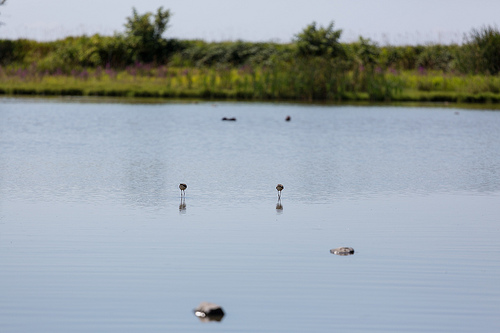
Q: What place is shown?
A: It is a lake.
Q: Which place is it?
A: It is a lake.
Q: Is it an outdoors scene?
A: Yes, it is outdoors.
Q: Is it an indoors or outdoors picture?
A: It is outdoors.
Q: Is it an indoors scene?
A: No, it is outdoors.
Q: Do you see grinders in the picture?
A: No, there are no grinders.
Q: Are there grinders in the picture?
A: No, there are no grinders.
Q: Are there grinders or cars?
A: No, there are no grinders or cars.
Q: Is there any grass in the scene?
A: Yes, there is grass.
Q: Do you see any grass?
A: Yes, there is grass.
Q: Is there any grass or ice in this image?
A: Yes, there is grass.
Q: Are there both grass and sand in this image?
A: No, there is grass but no sand.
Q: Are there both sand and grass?
A: No, there is grass but no sand.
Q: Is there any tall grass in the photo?
A: Yes, there is tall grass.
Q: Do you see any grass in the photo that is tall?
A: Yes, there is grass that is tall.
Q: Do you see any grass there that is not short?
A: Yes, there is tall grass.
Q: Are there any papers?
A: No, there are no papers.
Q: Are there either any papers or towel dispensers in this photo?
A: No, there are no papers or towel dispensers.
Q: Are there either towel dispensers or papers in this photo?
A: No, there are no papers or towel dispensers.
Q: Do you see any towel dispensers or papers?
A: No, there are no papers or towel dispensers.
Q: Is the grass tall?
A: Yes, the grass is tall.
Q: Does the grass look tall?
A: Yes, the grass is tall.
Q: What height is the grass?
A: The grass is tall.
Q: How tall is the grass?
A: The grass is tall.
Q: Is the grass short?
A: No, the grass is tall.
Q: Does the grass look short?
A: No, the grass is tall.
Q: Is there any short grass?
A: No, there is grass but it is tall.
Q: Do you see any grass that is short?
A: No, there is grass but it is tall.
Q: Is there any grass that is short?
A: No, there is grass but it is tall.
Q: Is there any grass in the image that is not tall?
A: No, there is grass but it is tall.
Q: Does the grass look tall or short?
A: The grass is tall.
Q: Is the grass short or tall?
A: The grass is tall.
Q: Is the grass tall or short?
A: The grass is tall.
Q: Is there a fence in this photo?
A: No, there are no fences.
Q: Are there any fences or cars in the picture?
A: No, there are no fences or cars.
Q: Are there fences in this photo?
A: No, there are no fences.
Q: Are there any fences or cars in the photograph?
A: No, there are no fences or cars.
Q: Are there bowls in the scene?
A: No, there are no bowls.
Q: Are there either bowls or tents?
A: No, there are no bowls or tents.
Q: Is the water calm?
A: Yes, the water is calm.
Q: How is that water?
A: The water is calm.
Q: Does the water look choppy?
A: No, the water is calm.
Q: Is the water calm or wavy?
A: The water is calm.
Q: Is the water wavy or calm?
A: The water is calm.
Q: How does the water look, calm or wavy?
A: The water is calm.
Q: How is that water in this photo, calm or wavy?
A: The water is calm.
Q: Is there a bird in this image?
A: Yes, there is a bird.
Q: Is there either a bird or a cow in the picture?
A: Yes, there is a bird.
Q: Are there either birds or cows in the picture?
A: Yes, there is a bird.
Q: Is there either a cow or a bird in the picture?
A: Yes, there is a bird.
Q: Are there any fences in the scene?
A: No, there are no fences.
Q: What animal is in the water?
A: The bird is in the water.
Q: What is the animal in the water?
A: The animal is a bird.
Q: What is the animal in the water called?
A: The animal is a bird.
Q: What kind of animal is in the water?
A: The animal is a bird.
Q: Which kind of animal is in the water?
A: The animal is a bird.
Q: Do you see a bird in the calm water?
A: Yes, there is a bird in the water.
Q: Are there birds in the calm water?
A: Yes, there is a bird in the water.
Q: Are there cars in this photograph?
A: No, there are no cars.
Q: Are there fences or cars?
A: No, there are no cars or fences.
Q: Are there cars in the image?
A: No, there are no cars.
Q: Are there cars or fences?
A: No, there are no cars or fences.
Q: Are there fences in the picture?
A: No, there are no fences.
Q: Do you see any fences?
A: No, there are no fences.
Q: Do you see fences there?
A: No, there are no fences.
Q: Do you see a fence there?
A: No, there are no fences.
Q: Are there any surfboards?
A: No, there are no surfboards.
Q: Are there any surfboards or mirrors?
A: No, there are no surfboards or mirrors.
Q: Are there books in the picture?
A: No, there are no books.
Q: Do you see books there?
A: No, there are no books.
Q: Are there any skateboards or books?
A: No, there are no books or skateboards.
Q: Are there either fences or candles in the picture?
A: No, there are no fences or candles.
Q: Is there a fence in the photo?
A: No, there are no fences.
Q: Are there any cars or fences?
A: No, there are no fences or cars.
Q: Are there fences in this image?
A: No, there are no fences.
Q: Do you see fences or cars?
A: No, there are no fences or cars.